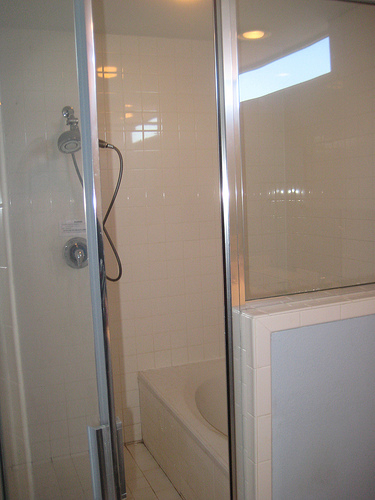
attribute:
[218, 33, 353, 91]
window — glass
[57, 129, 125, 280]
shower head — hand held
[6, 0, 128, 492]
door — glass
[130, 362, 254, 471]
bath tub — tan, ceramic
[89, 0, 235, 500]
door — silver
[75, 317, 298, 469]
tub — round